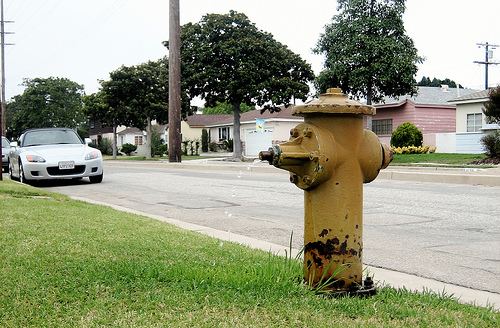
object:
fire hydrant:
[259, 81, 396, 300]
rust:
[306, 230, 358, 266]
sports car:
[3, 122, 108, 183]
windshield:
[23, 130, 81, 143]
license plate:
[54, 160, 79, 169]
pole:
[161, 0, 187, 160]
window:
[457, 109, 484, 137]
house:
[443, 84, 499, 153]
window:
[369, 116, 394, 136]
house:
[365, 84, 454, 150]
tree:
[180, 8, 301, 162]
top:
[212, 10, 257, 28]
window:
[211, 127, 230, 141]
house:
[191, 108, 304, 152]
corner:
[452, 101, 462, 152]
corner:
[408, 106, 418, 130]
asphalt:
[163, 192, 253, 210]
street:
[81, 156, 499, 290]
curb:
[66, 194, 484, 320]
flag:
[252, 116, 265, 133]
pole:
[472, 37, 499, 90]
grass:
[3, 179, 294, 327]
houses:
[92, 79, 497, 155]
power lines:
[444, 38, 499, 59]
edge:
[398, 158, 478, 163]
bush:
[389, 122, 421, 145]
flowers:
[390, 144, 439, 157]